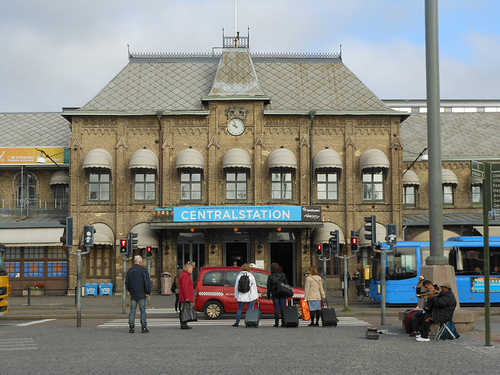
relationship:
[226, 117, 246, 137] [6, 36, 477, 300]
clock on building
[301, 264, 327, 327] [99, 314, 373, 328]
person waiting at crosswalk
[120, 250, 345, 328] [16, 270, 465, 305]
5 people crossing street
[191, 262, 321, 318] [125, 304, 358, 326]
van on crosswalk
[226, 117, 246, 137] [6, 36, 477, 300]
clock on  a building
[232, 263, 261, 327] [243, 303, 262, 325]
person carrying suitcase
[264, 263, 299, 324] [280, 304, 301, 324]
woman carrying suitcase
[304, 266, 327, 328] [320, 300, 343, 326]
person carrying suitcase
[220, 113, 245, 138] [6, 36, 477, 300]
clock on building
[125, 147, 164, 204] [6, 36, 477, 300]
window in building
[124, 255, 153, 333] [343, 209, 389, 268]
man crossing light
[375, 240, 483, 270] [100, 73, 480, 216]
bus near building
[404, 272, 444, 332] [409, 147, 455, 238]
people sitting next pole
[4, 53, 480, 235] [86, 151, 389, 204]
building with windows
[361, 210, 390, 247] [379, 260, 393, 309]
light on pole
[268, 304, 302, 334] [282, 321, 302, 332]
suitcase on wheels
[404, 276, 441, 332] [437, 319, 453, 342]
people sitting in chairs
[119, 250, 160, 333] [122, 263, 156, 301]
man wears jacket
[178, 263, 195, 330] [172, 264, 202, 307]
pedestrians wears jacket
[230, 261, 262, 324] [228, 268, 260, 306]
person wears jacket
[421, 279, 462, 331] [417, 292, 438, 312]
man plays instrument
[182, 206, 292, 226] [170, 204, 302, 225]
central station says on sign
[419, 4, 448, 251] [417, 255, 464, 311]
pole on cement block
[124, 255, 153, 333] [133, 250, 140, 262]
man has hair